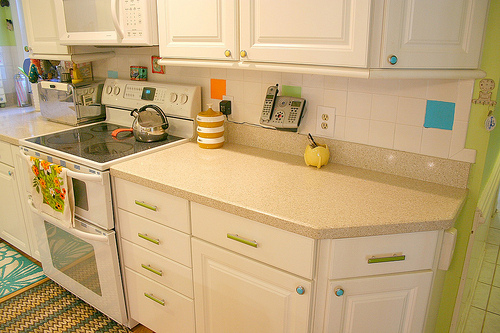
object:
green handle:
[367, 254, 406, 264]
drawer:
[325, 229, 442, 280]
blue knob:
[388, 54, 399, 65]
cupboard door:
[378, 0, 489, 71]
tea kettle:
[130, 104, 169, 143]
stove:
[19, 77, 203, 332]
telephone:
[260, 83, 307, 131]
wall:
[9, 3, 499, 332]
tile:
[372, 94, 397, 122]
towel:
[26, 153, 74, 229]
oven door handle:
[20, 153, 100, 183]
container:
[195, 107, 226, 150]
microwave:
[56, 1, 160, 48]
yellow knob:
[240, 50, 248, 58]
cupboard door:
[237, 0, 370, 71]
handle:
[226, 234, 258, 248]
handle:
[137, 233, 159, 245]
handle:
[141, 264, 162, 276]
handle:
[144, 293, 165, 306]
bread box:
[37, 79, 105, 127]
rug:
[2, 277, 133, 331]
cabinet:
[112, 171, 195, 331]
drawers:
[110, 178, 190, 235]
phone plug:
[220, 100, 231, 115]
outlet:
[222, 95, 233, 116]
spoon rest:
[111, 128, 134, 136]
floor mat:
[0, 240, 47, 300]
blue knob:
[334, 287, 345, 296]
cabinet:
[321, 278, 432, 332]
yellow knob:
[224, 50, 231, 57]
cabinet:
[157, 1, 244, 64]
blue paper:
[423, 99, 456, 131]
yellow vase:
[304, 143, 330, 169]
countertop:
[109, 113, 473, 240]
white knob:
[106, 85, 113, 94]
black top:
[24, 122, 185, 166]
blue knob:
[296, 285, 306, 295]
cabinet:
[191, 236, 313, 332]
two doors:
[20, 145, 129, 327]